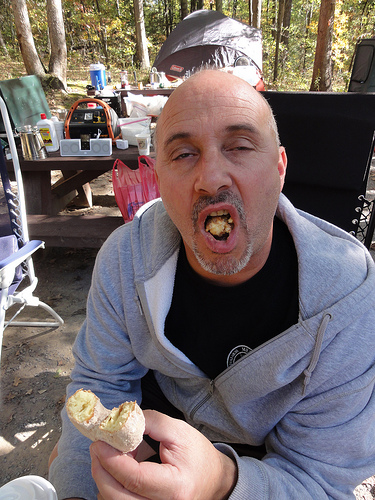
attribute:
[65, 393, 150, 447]
donut — partially eaten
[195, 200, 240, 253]
mouth — open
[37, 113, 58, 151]
white bottle — plastic 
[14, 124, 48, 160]
coffee pot — metal, silver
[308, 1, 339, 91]
tree trunk — large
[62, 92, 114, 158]
device — music playing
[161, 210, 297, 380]
tee shirt — black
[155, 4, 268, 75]
tent — gray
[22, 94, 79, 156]
bottle — lighter fluid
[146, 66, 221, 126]
wall — powdered sugar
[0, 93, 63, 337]
chair — white, metal, outdoor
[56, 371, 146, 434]
donut — partially eaten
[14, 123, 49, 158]
kettle — silver, metal, tea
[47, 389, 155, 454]
donut — bitten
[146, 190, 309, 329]
shirt — black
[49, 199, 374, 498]
sweatshirt — gray, hooded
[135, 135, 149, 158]
cup — white, brown, disposable, coffee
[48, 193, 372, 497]
jacket — gray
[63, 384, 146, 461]
donut — partial, eaten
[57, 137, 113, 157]
speakers — white 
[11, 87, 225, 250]
table — wooden, picnic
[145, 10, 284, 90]
camping tent — gray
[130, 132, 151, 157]
cup — styrofoam 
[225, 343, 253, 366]
logo —  white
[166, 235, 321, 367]
black shirt —  black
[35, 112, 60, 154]
bottle — white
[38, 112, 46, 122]
cap — red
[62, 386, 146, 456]
donut — white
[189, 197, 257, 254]
mouth — open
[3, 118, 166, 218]
table — picnic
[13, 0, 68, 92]
trunk — tree, double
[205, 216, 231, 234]
food — half eaten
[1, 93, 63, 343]
base — white, metal